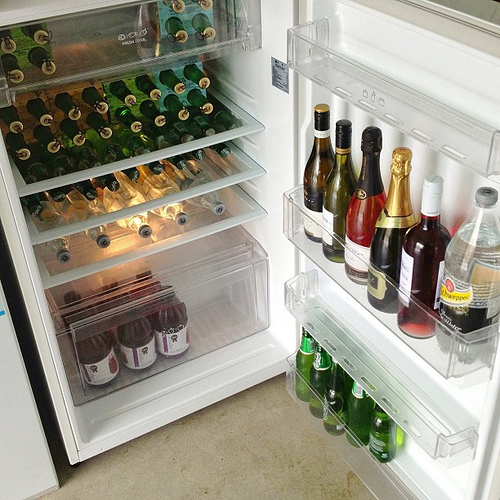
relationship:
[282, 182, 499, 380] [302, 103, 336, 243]
door shelf has bottle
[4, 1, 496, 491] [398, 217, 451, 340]
refrigerator has wine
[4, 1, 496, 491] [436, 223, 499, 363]
refrigerator has tonic water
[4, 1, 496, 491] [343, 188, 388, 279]
refrigerator has wine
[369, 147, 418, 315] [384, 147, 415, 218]
wine bottle has foil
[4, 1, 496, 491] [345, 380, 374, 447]
refrigerator has bottle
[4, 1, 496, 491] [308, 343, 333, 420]
refrigerator has bottle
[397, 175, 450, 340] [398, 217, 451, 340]
bottle has wine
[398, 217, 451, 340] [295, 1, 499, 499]
wine sitting in door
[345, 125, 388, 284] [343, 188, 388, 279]
bottle has wine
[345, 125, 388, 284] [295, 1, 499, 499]
bottle sitting in door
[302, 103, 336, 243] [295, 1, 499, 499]
bottle sitting in door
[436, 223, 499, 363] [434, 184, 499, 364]
tonic water held in bottle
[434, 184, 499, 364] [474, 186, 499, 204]
bottle has cap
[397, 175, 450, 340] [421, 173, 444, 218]
bottle has cap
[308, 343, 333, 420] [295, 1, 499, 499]
bottle sitting in door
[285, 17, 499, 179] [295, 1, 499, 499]
door shelf inside of door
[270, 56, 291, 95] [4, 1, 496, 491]
label inside of refrigerator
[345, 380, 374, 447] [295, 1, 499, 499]
bottle sitting in door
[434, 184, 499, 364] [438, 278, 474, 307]
bottle with label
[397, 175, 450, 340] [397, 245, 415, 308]
bottle has label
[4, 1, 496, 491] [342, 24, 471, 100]
refrigerator half empty